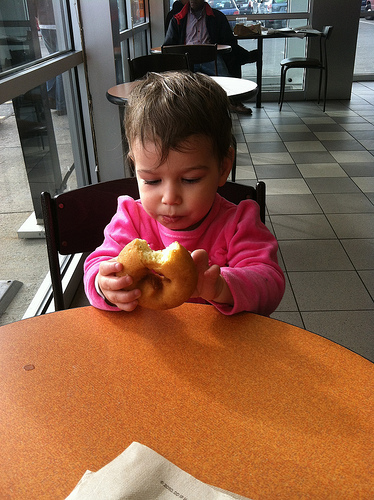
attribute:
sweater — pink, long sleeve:
[82, 189, 284, 317]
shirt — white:
[168, 8, 224, 47]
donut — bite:
[113, 240, 195, 312]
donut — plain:
[121, 237, 202, 323]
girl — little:
[52, 75, 278, 298]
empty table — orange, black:
[106, 71, 260, 103]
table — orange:
[0, 301, 371, 498]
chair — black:
[34, 170, 280, 305]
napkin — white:
[57, 441, 249, 496]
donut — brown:
[111, 239, 206, 317]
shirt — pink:
[79, 184, 289, 323]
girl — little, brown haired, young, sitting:
[74, 62, 294, 319]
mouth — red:
[156, 210, 192, 224]